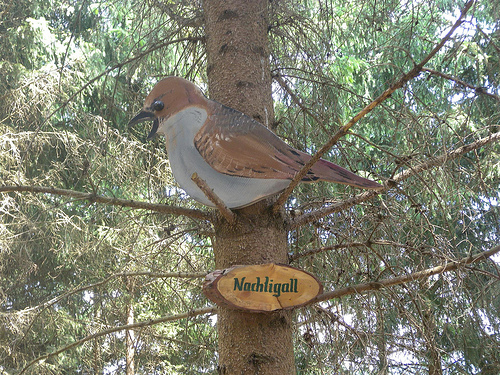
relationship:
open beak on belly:
[126, 110, 158, 140] [177, 158, 281, 208]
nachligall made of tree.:
[234, 272, 298, 298] [114, 19, 376, 372]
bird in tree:
[127, 71, 384, 220] [210, 10, 285, 98]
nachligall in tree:
[234, 272, 298, 298] [210, 10, 285, 98]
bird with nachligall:
[127, 71, 384, 220] [234, 272, 298, 298]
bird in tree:
[127, 76, 385, 220] [142, 5, 331, 369]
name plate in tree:
[209, 272, 319, 310] [142, 5, 331, 369]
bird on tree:
[127, 71, 384, 220] [1, 2, 498, 372]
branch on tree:
[272, 1, 472, 211] [1, 2, 498, 372]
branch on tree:
[293, 128, 498, 228] [1, 2, 498, 372]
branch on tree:
[289, 238, 499, 281] [1, 2, 498, 372]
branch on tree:
[322, 241, 500, 303] [1, 2, 498, 372]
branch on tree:
[4, 180, 213, 218] [1, 2, 498, 372]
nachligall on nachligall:
[234, 272, 299, 295] [234, 272, 298, 298]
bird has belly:
[127, 76, 385, 220] [162, 151, 280, 208]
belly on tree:
[177, 158, 281, 208] [204, 0, 300, 373]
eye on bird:
[141, 94, 188, 124] [127, 76, 385, 220]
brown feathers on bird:
[194, 104, 383, 189] [127, 76, 385, 220]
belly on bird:
[177, 158, 281, 208] [120, 75, 355, 260]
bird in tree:
[127, 71, 384, 220] [1, 2, 498, 372]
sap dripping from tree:
[244, 350, 267, 364] [201, 11, 309, 373]